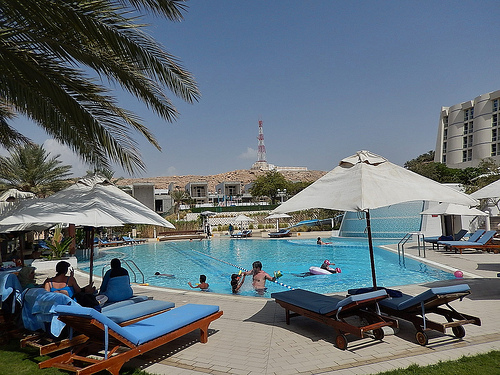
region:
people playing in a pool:
[148, 240, 368, 296]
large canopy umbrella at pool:
[257, 127, 478, 363]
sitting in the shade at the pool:
[28, 169, 182, 349]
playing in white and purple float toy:
[297, 257, 351, 282]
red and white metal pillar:
[247, 105, 282, 176]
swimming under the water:
[150, 266, 193, 296]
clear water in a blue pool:
[93, 231, 462, 333]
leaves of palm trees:
[15, 93, 170, 197]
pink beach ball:
[438, 262, 473, 285]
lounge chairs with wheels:
[270, 277, 480, 362]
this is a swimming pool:
[157, 239, 258, 261]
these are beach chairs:
[271, 275, 453, 342]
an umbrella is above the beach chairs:
[273, 152, 442, 225]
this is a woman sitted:
[103, 257, 125, 295]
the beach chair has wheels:
[331, 329, 388, 351]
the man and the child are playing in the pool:
[220, 255, 277, 295]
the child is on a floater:
[311, 254, 337, 280]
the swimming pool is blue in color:
[185, 241, 281, 257]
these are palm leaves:
[0, 1, 172, 156]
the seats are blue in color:
[118, 306, 190, 326]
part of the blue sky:
[264, 5, 394, 102]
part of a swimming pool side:
[245, 321, 292, 359]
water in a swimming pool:
[270, 245, 300, 269]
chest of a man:
[248, 273, 265, 283]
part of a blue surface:
[146, 313, 173, 329]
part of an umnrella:
[360, 166, 396, 198]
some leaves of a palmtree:
[72, 108, 149, 181]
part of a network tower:
[248, 117, 269, 159]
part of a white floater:
[312, 267, 329, 274]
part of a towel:
[110, 280, 128, 304]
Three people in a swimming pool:
[194, 258, 283, 298]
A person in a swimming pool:
[311, 230, 429, 264]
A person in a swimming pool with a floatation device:
[287, 251, 362, 293]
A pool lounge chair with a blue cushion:
[50, 298, 245, 368]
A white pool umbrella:
[310, 128, 443, 361]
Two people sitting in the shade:
[12, 178, 177, 330]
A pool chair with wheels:
[268, 283, 400, 362]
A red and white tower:
[237, 98, 283, 177]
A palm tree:
[8, 135, 69, 216]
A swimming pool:
[77, 219, 479, 315]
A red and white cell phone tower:
[253, 120, 267, 166]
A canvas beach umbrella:
[268, 149, 473, 212]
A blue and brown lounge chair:
[35, 300, 223, 372]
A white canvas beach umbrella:
[1, 172, 173, 226]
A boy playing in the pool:
[240, 261, 281, 289]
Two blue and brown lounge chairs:
[438, 230, 498, 255]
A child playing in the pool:
[230, 272, 245, 293]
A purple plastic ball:
[452, 269, 464, 279]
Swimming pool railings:
[399, 230, 424, 258]